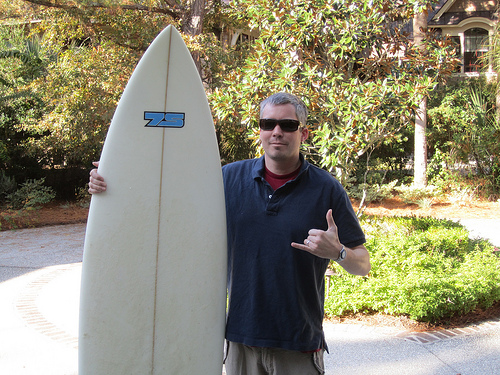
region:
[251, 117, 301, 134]
The sunglasses the man is wearing.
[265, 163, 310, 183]
The burgundy under shirt the man is wearing.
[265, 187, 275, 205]
The button on the blue shirt.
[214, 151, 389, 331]
The dark blue shirt the man is wearing.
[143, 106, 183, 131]
The sticker on the white surfboard.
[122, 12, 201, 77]
The tip of the surfboard.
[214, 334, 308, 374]
The beige pants the man is wearing.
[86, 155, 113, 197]
The guy's hand on the surfboard.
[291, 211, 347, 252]
The guy's right hand.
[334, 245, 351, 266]
The watch on the man's wrist.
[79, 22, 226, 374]
a large white surfboard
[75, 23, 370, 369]
a man holding a surfboard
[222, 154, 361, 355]
a dark blue polo shirt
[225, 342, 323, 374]
a pair of men's khaki pants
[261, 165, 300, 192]
a dark red t-shirt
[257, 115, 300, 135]
a pair of sunglasses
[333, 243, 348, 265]
a man's wrist watch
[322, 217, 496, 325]
a small green bush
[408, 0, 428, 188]
a tall tree trunk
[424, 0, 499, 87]
a building in distance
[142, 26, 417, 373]
man is holding a surfboard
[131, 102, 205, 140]
blue 75 on his surfboard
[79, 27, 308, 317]
surfboard is white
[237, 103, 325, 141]
man is wearing sunglasses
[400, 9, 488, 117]
house behind the tree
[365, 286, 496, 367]
bricks around the shrubs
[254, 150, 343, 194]
man has a red t-shirt under his shirt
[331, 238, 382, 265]
man is wearing a watch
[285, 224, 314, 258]
man is wearing a wedding band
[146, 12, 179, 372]
a line is going through the middle of surfboard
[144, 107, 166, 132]
the blue number 7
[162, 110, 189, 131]
the blue letter s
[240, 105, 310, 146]
these are sun glasses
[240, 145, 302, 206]
this is an undershirt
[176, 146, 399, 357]
this is a shirt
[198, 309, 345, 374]
these are the pants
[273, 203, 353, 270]
this is a hand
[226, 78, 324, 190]
this is a head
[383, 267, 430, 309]
these are green leaves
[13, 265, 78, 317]
this is the concrete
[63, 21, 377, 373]
the man loves his surfboard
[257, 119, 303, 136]
the man has sunglasses on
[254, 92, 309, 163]
the man has gray hair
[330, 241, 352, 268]
the man is wearing a watch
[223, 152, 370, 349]
the man is wearing a blue polo shirt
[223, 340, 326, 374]
khaki pants are on the man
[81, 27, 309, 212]
the man has a hand around the surfboard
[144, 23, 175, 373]
a red stringer is through the surfboard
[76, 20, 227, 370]
the board is white with a design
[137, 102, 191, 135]
the design is a blue logo